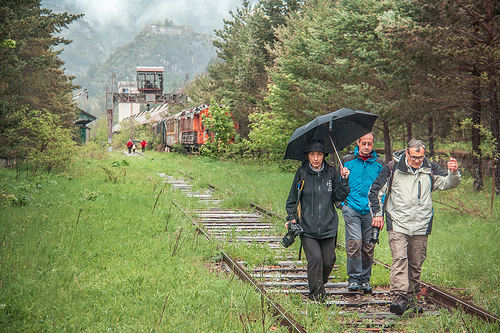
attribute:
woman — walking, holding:
[283, 142, 349, 298]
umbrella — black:
[284, 109, 377, 155]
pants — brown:
[389, 232, 428, 293]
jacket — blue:
[343, 152, 387, 216]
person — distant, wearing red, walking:
[139, 141, 149, 152]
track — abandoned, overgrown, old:
[175, 181, 283, 242]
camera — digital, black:
[280, 219, 305, 250]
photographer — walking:
[370, 139, 464, 300]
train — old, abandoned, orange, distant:
[151, 107, 231, 155]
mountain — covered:
[133, 18, 218, 66]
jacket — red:
[127, 141, 132, 150]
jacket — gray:
[367, 160, 468, 236]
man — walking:
[343, 132, 386, 290]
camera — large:
[369, 226, 387, 246]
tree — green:
[2, 0, 75, 171]